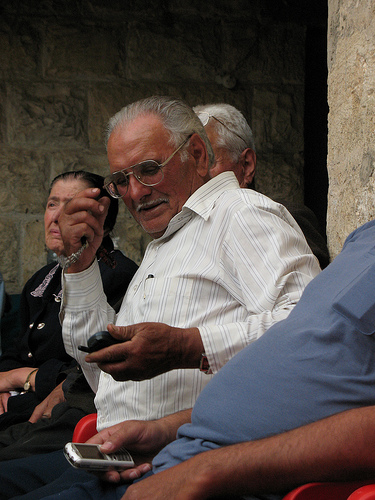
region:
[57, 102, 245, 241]
old man wearing glasses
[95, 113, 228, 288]
old man looking at phone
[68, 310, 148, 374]
phone in man's hand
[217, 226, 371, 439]
blue shirt on man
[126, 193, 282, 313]
white shirt on man's body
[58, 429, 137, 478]
light phone in man's hand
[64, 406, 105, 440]
part of the red chair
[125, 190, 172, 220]
mustache above man's lip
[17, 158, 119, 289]
woman next to man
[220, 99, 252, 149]
gray hair on man's head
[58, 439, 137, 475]
silver and black cell phone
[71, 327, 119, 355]
black cell phone with black antenna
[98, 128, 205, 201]
metal frame eye glasses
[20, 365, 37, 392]
wrist watch with thin band and white face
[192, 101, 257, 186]
man with eye glasses propped up on head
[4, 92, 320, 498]
man in striped shirt sitting and looking down at cell phone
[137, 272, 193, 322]
black ink pen in collared shirt front pocket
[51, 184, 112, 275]
hand holding metal wrist watch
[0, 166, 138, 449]
woman in black outfit sitting with both hands folded over in lap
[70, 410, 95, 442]
red chair armrest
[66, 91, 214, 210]
a man wearing glasses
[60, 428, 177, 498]
a silver cell phone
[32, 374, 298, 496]
someone holding a silver cell phone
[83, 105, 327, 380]
a man wearing a white long sleeve shirt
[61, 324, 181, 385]
a black cell phone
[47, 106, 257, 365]
a man holding a black cell phone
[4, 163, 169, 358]
a person wearing a black long sleeve shirt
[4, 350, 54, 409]
a watch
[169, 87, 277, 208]
a person with glasses on their head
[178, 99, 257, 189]
a person with grey hair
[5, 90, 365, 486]
several old men are sitting outside holding cell phones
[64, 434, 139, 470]
a silver cell phone a man is holding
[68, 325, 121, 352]
a black cell phone a man is holding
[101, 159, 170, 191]
large wire-rimmed eyeglasses the man is wearing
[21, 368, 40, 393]
a silver watch a man is wearing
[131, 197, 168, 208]
a thin grey mustache the man has on his face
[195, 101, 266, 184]
the grey-haired head of a man behind another man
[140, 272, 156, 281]
the top of a black pen in the man's shirt pocket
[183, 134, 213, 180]
The old man's left ear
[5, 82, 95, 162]
an old stone wall near where the men are seated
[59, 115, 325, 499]
man has cream and white shirt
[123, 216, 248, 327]
shirt has grey stripes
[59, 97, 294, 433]
man has silver hair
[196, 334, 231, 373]
watch peaking out from shirt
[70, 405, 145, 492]
man has cellphone in hand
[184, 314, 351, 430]
man has blue shirt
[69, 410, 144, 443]
seats are red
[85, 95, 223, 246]
man has grey glasses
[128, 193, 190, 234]
man has thin grey mustache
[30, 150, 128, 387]
woman has black hair